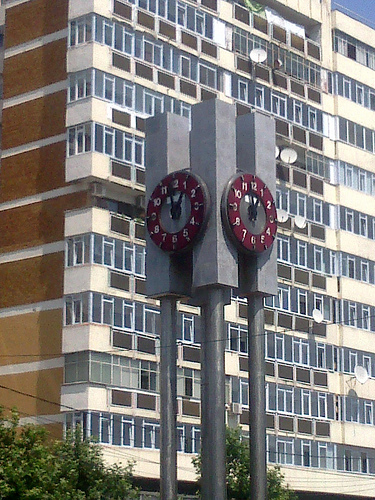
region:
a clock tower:
[143, 163, 216, 254]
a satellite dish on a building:
[241, 46, 273, 72]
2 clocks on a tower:
[148, 165, 280, 259]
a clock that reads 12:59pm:
[145, 174, 208, 254]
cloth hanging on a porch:
[244, 2, 317, 43]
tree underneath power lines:
[6, 415, 130, 499]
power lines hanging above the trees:
[0, 409, 370, 478]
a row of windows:
[90, 15, 226, 94]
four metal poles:
[153, 286, 270, 499]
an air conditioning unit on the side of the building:
[88, 178, 112, 199]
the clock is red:
[141, 159, 217, 265]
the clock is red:
[225, 174, 288, 253]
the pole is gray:
[147, 294, 174, 499]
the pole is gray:
[185, 293, 243, 498]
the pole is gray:
[230, 300, 271, 498]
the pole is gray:
[150, 297, 196, 492]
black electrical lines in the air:
[14, 337, 152, 424]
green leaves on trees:
[51, 441, 104, 471]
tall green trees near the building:
[25, 420, 119, 484]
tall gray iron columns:
[137, 304, 292, 465]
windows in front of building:
[98, 410, 139, 446]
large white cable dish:
[338, 359, 374, 391]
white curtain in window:
[124, 304, 140, 328]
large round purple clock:
[220, 168, 293, 271]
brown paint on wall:
[12, 322, 54, 346]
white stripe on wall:
[9, 350, 69, 381]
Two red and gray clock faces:
[144, 167, 279, 255]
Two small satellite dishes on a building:
[310, 307, 367, 386]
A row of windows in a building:
[90, 9, 294, 114]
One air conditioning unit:
[225, 398, 240, 413]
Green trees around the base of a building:
[0, 411, 291, 492]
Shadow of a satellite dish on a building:
[340, 365, 364, 401]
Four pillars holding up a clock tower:
[138, 165, 273, 489]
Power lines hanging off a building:
[0, 341, 150, 442]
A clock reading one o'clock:
[141, 166, 201, 242]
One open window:
[64, 295, 87, 326]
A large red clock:
[144, 168, 212, 255]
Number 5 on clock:
[181, 228, 189, 237]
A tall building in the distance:
[0, 0, 373, 499]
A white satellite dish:
[250, 47, 267, 63]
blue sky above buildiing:
[330, 0, 373, 29]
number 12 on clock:
[251, 180, 258, 190]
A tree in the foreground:
[0, 404, 152, 499]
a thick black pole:
[153, 295, 177, 499]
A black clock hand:
[248, 188, 258, 220]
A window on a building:
[89, 350, 112, 385]